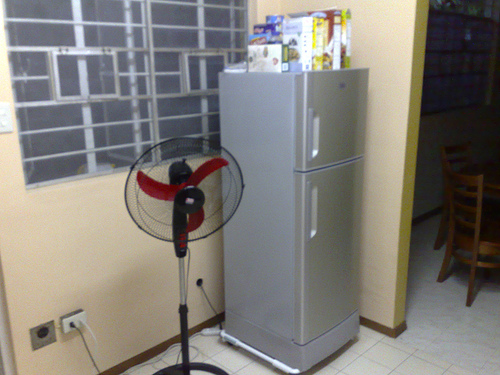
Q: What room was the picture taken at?
A: It was taken at the kitchen.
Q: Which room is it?
A: It is a kitchen.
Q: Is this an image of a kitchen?
A: Yes, it is showing a kitchen.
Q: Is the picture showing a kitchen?
A: Yes, it is showing a kitchen.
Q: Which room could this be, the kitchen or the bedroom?
A: It is the kitchen.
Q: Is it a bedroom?
A: No, it is a kitchen.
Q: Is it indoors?
A: Yes, it is indoors.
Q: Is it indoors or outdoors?
A: It is indoors.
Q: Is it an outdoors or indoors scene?
A: It is indoors.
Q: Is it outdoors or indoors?
A: It is indoors.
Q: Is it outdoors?
A: No, it is indoors.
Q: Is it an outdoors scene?
A: No, it is indoors.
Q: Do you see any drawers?
A: No, there are no drawers.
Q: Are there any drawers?
A: No, there are no drawers.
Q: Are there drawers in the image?
A: No, there are no drawers.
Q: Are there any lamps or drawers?
A: No, there are no drawers or lamps.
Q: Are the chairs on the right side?
A: Yes, the chairs are on the right of the image.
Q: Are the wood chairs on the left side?
A: No, the chairs are on the right of the image.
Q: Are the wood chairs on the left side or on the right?
A: The chairs are on the right of the image.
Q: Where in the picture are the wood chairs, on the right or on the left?
A: The chairs are on the right of the image.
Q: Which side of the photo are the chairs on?
A: The chairs are on the right of the image.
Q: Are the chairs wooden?
A: Yes, the chairs are wooden.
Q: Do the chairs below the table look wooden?
A: Yes, the chairs are wooden.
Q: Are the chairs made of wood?
A: Yes, the chairs are made of wood.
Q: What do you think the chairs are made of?
A: The chairs are made of wood.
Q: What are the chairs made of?
A: The chairs are made of wood.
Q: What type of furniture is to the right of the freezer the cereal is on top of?
A: The pieces of furniture are chairs.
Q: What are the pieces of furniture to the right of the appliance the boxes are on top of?
A: The pieces of furniture are chairs.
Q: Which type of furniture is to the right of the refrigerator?
A: The pieces of furniture are chairs.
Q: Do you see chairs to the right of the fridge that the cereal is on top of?
A: Yes, there are chairs to the right of the fridge.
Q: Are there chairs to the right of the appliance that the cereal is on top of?
A: Yes, there are chairs to the right of the fridge.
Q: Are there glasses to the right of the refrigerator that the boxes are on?
A: No, there are chairs to the right of the freezer.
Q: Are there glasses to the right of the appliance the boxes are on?
A: No, there are chairs to the right of the freezer.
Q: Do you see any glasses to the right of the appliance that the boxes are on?
A: No, there are chairs to the right of the freezer.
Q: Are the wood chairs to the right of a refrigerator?
A: Yes, the chairs are to the right of a refrigerator.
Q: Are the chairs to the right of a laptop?
A: No, the chairs are to the right of a refrigerator.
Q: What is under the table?
A: The chairs are under the table.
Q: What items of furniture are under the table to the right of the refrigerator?
A: The pieces of furniture are chairs.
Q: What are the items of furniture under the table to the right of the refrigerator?
A: The pieces of furniture are chairs.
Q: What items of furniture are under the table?
A: The pieces of furniture are chairs.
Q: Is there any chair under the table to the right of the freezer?
A: Yes, there are chairs under the table.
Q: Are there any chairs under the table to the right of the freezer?
A: Yes, there are chairs under the table.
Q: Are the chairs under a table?
A: Yes, the chairs are under a table.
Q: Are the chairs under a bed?
A: No, the chairs are under a table.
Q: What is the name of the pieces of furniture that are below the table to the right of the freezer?
A: The pieces of furniture are chairs.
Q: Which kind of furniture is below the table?
A: The pieces of furniture are chairs.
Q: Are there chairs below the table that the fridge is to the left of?
A: Yes, there are chairs below the table.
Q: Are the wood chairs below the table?
A: Yes, the chairs are below the table.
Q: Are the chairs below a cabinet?
A: No, the chairs are below the table.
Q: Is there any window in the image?
A: Yes, there is a window.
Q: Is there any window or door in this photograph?
A: Yes, there is a window.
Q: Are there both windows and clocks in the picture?
A: No, there is a window but no clocks.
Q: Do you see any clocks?
A: No, there are no clocks.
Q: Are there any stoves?
A: No, there are no stoves.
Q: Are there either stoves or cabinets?
A: No, there are no stoves or cabinets.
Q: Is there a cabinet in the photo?
A: No, there are no cabinets.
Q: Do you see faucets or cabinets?
A: No, there are no cabinets or faucets.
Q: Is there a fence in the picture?
A: No, there are no fences.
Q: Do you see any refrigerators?
A: Yes, there is a refrigerator.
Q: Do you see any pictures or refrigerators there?
A: Yes, there is a refrigerator.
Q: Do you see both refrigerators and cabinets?
A: No, there is a refrigerator but no cabinets.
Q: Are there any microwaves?
A: No, there are no microwaves.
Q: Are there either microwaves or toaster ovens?
A: No, there are no microwaves or toaster ovens.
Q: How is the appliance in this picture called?
A: The appliance is a refrigerator.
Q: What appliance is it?
A: The appliance is a refrigerator.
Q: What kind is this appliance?
A: This is a refrigerator.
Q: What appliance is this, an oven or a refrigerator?
A: This is a refrigerator.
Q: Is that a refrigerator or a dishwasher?
A: That is a refrigerator.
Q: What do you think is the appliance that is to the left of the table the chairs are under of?
A: The appliance is a refrigerator.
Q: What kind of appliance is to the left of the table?
A: The appliance is a refrigerator.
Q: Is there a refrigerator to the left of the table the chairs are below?
A: Yes, there is a refrigerator to the left of the table.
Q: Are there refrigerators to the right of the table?
A: No, the refrigerator is to the left of the table.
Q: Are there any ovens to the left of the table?
A: No, there is a refrigerator to the left of the table.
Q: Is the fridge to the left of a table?
A: Yes, the fridge is to the left of a table.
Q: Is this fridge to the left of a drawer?
A: No, the fridge is to the left of a table.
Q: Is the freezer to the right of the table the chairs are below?
A: No, the freezer is to the left of the table.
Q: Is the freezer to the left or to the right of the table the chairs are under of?
A: The freezer is to the left of the table.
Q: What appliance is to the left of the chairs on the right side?
A: The appliance is a refrigerator.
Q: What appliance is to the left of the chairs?
A: The appliance is a refrigerator.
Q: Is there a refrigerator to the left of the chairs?
A: Yes, there is a refrigerator to the left of the chairs.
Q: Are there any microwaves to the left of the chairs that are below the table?
A: No, there is a refrigerator to the left of the chairs.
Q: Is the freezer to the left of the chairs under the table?
A: Yes, the freezer is to the left of the chairs.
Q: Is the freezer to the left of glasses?
A: No, the freezer is to the left of the chairs.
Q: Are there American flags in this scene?
A: No, there are no American flags.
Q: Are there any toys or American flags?
A: No, there are no American flags or toys.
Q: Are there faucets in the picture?
A: No, there are no faucets.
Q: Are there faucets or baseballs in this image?
A: No, there are no faucets or baseballs.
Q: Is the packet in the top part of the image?
A: Yes, the packet is in the top of the image.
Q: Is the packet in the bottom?
A: No, the packet is in the top of the image.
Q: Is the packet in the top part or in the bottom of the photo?
A: The packet is in the top of the image.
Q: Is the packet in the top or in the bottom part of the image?
A: The packet is in the top of the image.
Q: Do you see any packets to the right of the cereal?
A: Yes, there is a packet to the right of the cereal.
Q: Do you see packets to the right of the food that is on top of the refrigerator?
A: Yes, there is a packet to the right of the cereal.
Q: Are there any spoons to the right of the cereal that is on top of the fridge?
A: No, there is a packet to the right of the cereal.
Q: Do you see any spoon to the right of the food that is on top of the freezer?
A: No, there is a packet to the right of the cereal.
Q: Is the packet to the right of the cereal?
A: Yes, the packet is to the right of the cereal.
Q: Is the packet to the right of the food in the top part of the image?
A: Yes, the packet is to the right of the cereal.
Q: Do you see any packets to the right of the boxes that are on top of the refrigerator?
A: Yes, there is a packet to the right of the boxes.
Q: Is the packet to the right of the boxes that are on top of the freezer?
A: Yes, the packet is to the right of the boxes.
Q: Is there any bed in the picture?
A: No, there are no beds.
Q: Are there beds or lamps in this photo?
A: No, there are no beds or lamps.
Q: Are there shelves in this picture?
A: No, there are no shelves.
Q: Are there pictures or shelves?
A: No, there are no shelves or pictures.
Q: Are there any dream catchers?
A: No, there are no dream catchers.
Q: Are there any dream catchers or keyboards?
A: No, there are no dream catchers or keyboards.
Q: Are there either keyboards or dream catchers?
A: No, there are no dream catchers or keyboards.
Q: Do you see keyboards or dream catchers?
A: No, there are no dream catchers or keyboards.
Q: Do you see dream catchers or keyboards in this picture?
A: No, there are no dream catchers or keyboards.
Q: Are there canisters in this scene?
A: No, there are no canisters.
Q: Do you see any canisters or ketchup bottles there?
A: No, there are no canisters or ketchup bottles.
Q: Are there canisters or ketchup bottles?
A: No, there are no canisters or ketchup bottles.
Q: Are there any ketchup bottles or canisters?
A: No, there are no canisters or ketchup bottles.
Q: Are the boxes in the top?
A: Yes, the boxes are in the top of the image.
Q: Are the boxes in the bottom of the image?
A: No, the boxes are in the top of the image.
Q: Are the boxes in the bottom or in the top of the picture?
A: The boxes are in the top of the image.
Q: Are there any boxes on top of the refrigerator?
A: Yes, there are boxes on top of the refrigerator.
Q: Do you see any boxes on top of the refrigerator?
A: Yes, there are boxes on top of the refrigerator.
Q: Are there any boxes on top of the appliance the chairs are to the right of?
A: Yes, there are boxes on top of the refrigerator.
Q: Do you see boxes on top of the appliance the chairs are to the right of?
A: Yes, there are boxes on top of the refrigerator.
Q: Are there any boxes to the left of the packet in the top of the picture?
A: Yes, there are boxes to the left of the packet.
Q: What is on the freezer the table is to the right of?
A: The boxes are on the refrigerator.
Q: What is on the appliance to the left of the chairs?
A: The boxes are on the refrigerator.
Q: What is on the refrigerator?
A: The boxes are on the refrigerator.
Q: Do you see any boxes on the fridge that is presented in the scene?
A: Yes, there are boxes on the fridge.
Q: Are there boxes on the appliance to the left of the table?
A: Yes, there are boxes on the fridge.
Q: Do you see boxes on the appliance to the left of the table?
A: Yes, there are boxes on the fridge.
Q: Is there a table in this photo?
A: Yes, there is a table.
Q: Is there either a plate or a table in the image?
A: Yes, there is a table.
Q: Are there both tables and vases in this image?
A: No, there is a table but no vases.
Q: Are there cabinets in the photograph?
A: No, there are no cabinets.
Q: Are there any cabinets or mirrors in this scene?
A: No, there are no cabinets or mirrors.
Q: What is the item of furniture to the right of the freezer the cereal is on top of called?
A: The piece of furniture is a table.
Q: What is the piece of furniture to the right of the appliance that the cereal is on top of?
A: The piece of furniture is a table.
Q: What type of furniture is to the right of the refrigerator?
A: The piece of furniture is a table.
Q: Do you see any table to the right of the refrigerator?
A: Yes, there is a table to the right of the refrigerator.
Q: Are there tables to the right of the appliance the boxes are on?
A: Yes, there is a table to the right of the refrigerator.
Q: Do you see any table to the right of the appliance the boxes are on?
A: Yes, there is a table to the right of the refrigerator.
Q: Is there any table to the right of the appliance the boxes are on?
A: Yes, there is a table to the right of the refrigerator.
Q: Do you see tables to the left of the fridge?
A: No, the table is to the right of the fridge.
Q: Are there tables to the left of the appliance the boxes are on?
A: No, the table is to the right of the fridge.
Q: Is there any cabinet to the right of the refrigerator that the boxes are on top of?
A: No, there is a table to the right of the refrigerator.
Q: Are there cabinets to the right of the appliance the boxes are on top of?
A: No, there is a table to the right of the refrigerator.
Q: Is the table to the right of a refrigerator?
A: Yes, the table is to the right of a refrigerator.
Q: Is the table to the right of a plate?
A: No, the table is to the right of a refrigerator.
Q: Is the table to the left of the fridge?
A: No, the table is to the right of the fridge.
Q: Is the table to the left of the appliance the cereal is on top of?
A: No, the table is to the right of the fridge.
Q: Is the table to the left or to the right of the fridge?
A: The table is to the right of the fridge.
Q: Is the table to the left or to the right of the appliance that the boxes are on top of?
A: The table is to the right of the fridge.